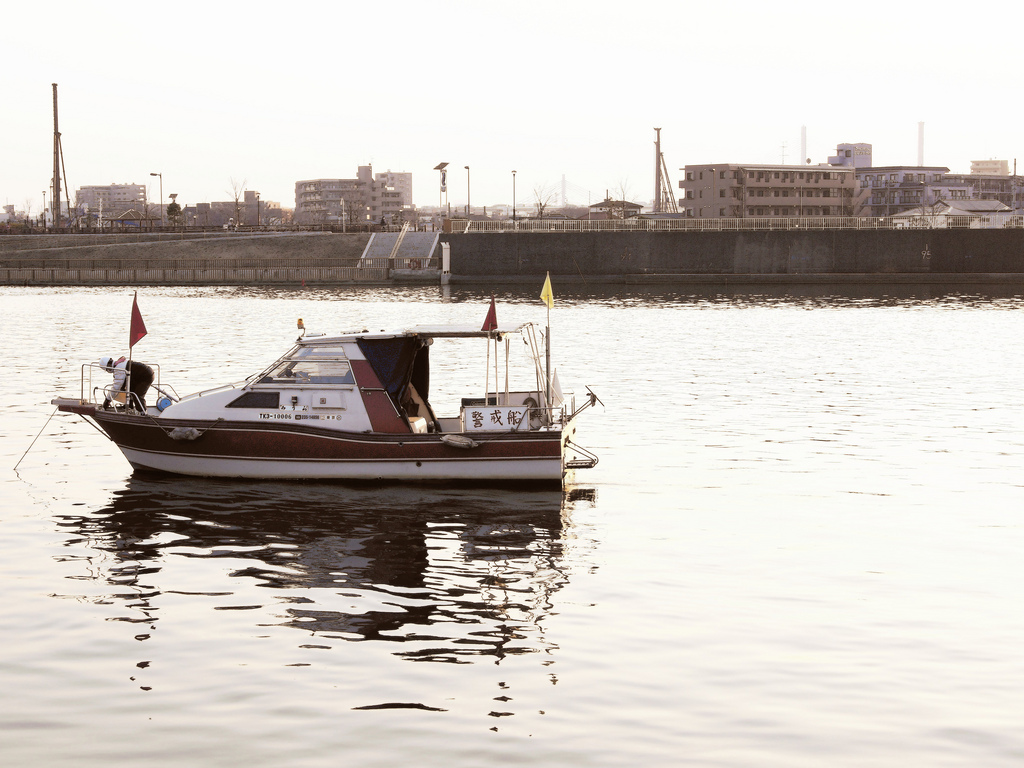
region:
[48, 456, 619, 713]
the water is reflecting the boat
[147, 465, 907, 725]
the water is calm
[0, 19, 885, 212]
the sky is overcast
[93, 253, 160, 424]
a red flag on the front of the boat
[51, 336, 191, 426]
a person is bending down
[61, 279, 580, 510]
the boat is maroon and white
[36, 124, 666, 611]
the boat is not moving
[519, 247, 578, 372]
the flag is yellow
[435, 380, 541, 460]
asian writing is on the boat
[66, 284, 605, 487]
Boat floating on water.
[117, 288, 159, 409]
Flag on a boat.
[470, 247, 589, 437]
Flags on a boat.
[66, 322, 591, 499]
Brown and white boat in water.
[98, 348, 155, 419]
Person standing on a boat.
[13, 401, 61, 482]
Chain connected to a boat.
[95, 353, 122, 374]
White hat on a person.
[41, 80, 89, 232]
Pole next to water.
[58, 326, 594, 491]
a small red and white boat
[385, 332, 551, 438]
the back cabin of a boat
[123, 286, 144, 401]
a small flag on a boat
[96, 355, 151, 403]
a man on a boat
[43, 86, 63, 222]
a tall metal pole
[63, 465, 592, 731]
the reflection of a boat in the water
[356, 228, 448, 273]
a large concrete ramp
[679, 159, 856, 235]
a brown four story building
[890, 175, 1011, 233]
a short white building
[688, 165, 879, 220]
A building in a city.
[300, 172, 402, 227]
A building in a city.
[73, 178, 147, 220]
A building in a city.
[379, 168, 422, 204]
A building in a city.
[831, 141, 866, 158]
A building in a city.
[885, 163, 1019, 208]
A building in a city.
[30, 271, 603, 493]
a small brown and white boat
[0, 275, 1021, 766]
a large body of water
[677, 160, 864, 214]
a brown building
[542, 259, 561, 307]
a small yellow flag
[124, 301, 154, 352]
a small red flag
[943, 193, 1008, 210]
a roof of a building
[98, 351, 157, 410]
a person bending down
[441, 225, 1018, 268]
a long barrier wall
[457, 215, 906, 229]
a long white rail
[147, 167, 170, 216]
a tall light pole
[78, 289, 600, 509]
a boat on the water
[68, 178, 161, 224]
a building in a city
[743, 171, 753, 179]
a window on a building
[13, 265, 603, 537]
Man on front of a boat with anchor set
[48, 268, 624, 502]
Red and white fishing boat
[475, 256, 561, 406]
Red and yellow colored flags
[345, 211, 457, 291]
Stairs with a center rail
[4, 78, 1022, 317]
Office buildings next to a river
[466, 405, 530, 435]
Red Asian writing on white background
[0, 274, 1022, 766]
Calm river water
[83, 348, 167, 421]
Man doing work on a boat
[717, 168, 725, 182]
A window on a building.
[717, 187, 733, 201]
A window on a building.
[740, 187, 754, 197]
A window on a building.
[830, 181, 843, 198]
A window on a building.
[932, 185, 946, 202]
A window on a building.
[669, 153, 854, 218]
A building in a city.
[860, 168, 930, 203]
A building in a city.